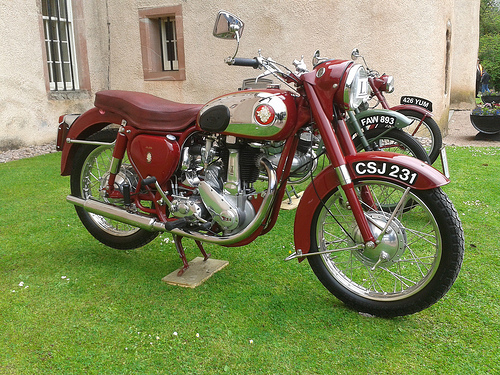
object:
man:
[476, 58, 483, 98]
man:
[479, 69, 492, 95]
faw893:
[360, 115, 395, 127]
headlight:
[362, 81, 372, 103]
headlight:
[385, 74, 395, 93]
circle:
[254, 103, 276, 127]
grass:
[370, 259, 500, 369]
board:
[160, 254, 228, 290]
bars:
[158, 16, 179, 71]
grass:
[193, 283, 296, 345]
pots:
[470, 113, 500, 142]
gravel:
[0, 142, 55, 164]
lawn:
[240, 237, 335, 284]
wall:
[96, 0, 209, 112]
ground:
[442, 107, 499, 146]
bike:
[167, 52, 431, 215]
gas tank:
[194, 88, 300, 141]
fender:
[293, 149, 452, 265]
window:
[37, 0, 83, 94]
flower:
[173, 331, 178, 335]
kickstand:
[170, 221, 210, 277]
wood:
[159, 246, 228, 290]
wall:
[231, 0, 479, 139]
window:
[155, 15, 178, 72]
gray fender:
[336, 107, 413, 143]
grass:
[2, 230, 65, 365]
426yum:
[402, 97, 429, 108]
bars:
[37, 0, 75, 92]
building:
[0, 5, 482, 153]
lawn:
[8, 165, 83, 240]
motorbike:
[232, 41, 445, 175]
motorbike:
[54, 11, 463, 319]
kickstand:
[282, 177, 301, 204]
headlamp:
[334, 59, 371, 112]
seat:
[93, 89, 211, 131]